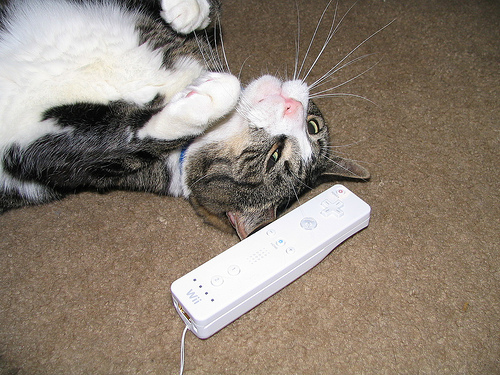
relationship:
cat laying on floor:
[0, 0, 397, 240] [2, 1, 499, 372]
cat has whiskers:
[4, 1, 381, 243] [310, 31, 381, 111]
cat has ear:
[4, 1, 381, 243] [313, 145, 379, 186]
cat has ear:
[4, 1, 381, 243] [213, 194, 283, 243]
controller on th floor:
[170, 184, 371, 375] [96, 97, 500, 372]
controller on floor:
[147, 171, 349, 333] [2, 1, 499, 372]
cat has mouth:
[4, 1, 381, 243] [256, 71, 293, 106]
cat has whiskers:
[4, 1, 381, 243] [192, 28, 397, 120]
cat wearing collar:
[0, 0, 397, 240] [176, 142, 189, 195]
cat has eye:
[4, 1, 381, 243] [266, 136, 291, 172]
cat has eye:
[0, 0, 397, 240] [305, 117, 321, 137]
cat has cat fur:
[4, 1, 381, 243] [0, 1, 205, 157]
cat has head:
[4, 1, 381, 243] [195, 71, 330, 214]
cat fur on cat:
[10, 22, 206, 156] [4, 1, 381, 243]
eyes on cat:
[251, 111, 325, 180] [11, 10, 369, 215]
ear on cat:
[315, 152, 384, 189] [4, 1, 381, 243]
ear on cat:
[217, 196, 278, 246] [4, 1, 381, 243]